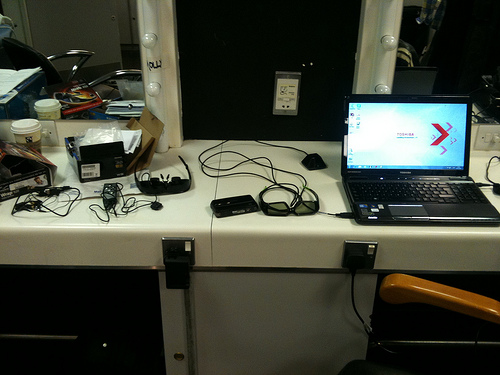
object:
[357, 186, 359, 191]
button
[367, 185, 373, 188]
button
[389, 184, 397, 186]
button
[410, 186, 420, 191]
button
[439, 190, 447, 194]
button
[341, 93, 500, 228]
computer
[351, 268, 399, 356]
wire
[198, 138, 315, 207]
black wire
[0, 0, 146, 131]
mirror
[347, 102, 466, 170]
glowing image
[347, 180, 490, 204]
black keyboard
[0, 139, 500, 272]
counter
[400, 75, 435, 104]
ground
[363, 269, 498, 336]
handle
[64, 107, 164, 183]
box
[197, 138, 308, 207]
wires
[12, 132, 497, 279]
table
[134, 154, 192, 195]
glasses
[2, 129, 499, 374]
desk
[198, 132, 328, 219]
cord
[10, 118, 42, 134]
lid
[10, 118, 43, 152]
coffee cup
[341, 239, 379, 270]
socket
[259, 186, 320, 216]
sunglasses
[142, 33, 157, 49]
bulb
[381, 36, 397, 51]
bulb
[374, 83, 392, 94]
bulb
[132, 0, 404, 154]
wall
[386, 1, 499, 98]
mirror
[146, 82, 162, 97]
bulb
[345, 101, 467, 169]
screen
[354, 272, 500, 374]
chair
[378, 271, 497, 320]
arm